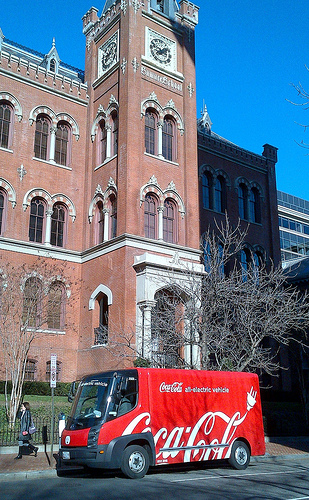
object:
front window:
[71, 377, 113, 420]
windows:
[163, 197, 178, 243]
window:
[144, 192, 158, 240]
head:
[22, 402, 28, 410]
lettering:
[122, 411, 248, 465]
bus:
[57, 367, 266, 478]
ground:
[0, 393, 309, 500]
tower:
[78, 0, 207, 375]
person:
[14, 402, 38, 460]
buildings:
[0, 0, 309, 404]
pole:
[50, 388, 53, 466]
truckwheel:
[229, 441, 250, 470]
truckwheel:
[121, 445, 150, 479]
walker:
[15, 402, 38, 459]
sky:
[0, 0, 309, 201]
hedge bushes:
[0, 380, 99, 395]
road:
[0, 439, 309, 500]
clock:
[144, 27, 177, 76]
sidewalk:
[0, 441, 309, 472]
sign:
[50, 353, 56, 388]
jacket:
[18, 409, 31, 441]